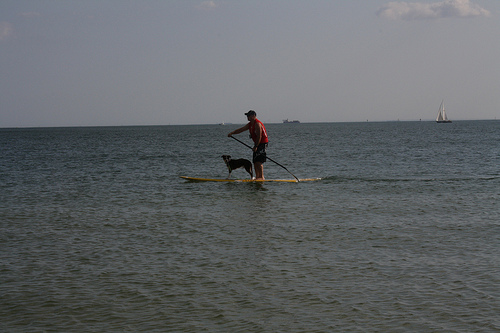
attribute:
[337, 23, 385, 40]
sky — blue, cloudy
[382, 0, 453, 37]
clouds — white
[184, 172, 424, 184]
surfboard — bamboo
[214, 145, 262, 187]
dog — black